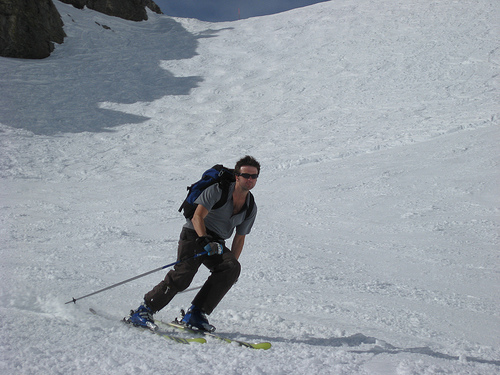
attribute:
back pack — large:
[176, 164, 234, 220]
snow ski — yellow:
[91, 291, 266, 363]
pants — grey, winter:
[143, 226, 242, 312]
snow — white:
[310, 95, 475, 217]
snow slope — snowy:
[5, 8, 498, 363]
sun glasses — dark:
[238, 159, 268, 195]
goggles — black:
[237, 168, 262, 180]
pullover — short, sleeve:
[183, 179, 258, 242]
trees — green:
[6, 1, 77, 75]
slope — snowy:
[0, 1, 489, 373]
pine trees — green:
[0, 3, 163, 66]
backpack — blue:
[182, 161, 233, 231]